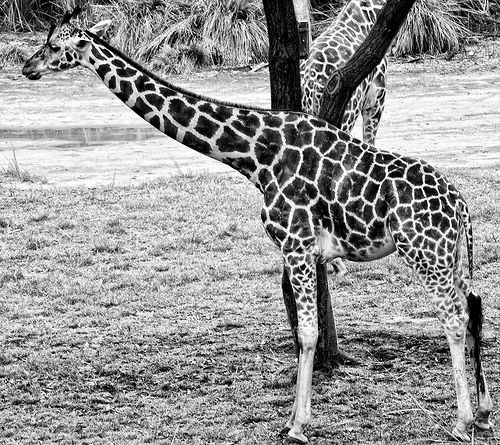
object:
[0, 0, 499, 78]
grass shrubs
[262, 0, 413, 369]
tree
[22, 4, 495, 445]
giraffe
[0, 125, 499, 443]
area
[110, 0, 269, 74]
big leaves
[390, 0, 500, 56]
big leaves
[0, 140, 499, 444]
grass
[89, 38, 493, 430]
fur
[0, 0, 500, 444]
ground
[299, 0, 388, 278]
giraffe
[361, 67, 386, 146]
leg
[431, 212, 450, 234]
patches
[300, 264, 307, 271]
patches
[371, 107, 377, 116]
patches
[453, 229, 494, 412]
leg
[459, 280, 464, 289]
patches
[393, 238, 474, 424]
leg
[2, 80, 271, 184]
moss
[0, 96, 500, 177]
pond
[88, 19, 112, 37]
ears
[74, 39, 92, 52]
ears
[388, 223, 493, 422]
back legs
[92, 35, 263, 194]
neck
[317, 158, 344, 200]
spots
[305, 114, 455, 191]
giraffe's back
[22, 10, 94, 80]
head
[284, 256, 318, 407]
leg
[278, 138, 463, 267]
skin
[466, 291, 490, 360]
hair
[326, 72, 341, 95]
cut branch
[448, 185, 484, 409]
tail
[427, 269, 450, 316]
fringes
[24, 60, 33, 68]
nose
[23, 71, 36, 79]
mouth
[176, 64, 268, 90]
dirt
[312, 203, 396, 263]
stomach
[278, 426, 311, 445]
feet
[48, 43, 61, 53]
eye